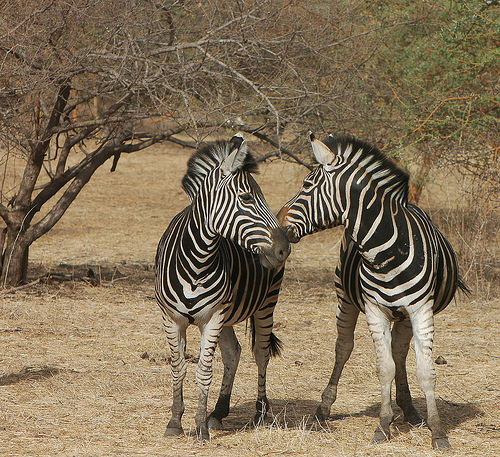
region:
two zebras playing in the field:
[181, 134, 416, 278]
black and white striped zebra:
[176, 132, 280, 439]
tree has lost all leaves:
[16, 30, 377, 127]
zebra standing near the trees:
[293, 130, 455, 394]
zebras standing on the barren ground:
[161, 139, 466, 445]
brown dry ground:
[27, 275, 153, 427]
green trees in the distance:
[231, 18, 484, 129]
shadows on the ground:
[159, 367, 498, 427]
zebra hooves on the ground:
[145, 379, 302, 448]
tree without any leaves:
[23, 66, 145, 304]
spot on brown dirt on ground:
[10, 353, 73, 397]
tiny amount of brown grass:
[244, 393, 326, 441]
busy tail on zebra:
[245, 326, 294, 362]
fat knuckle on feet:
[220, 337, 246, 367]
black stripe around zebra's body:
[153, 273, 220, 323]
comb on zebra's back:
[161, 118, 255, 194]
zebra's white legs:
[346, 287, 448, 420]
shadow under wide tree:
[6, 222, 157, 291]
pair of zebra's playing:
[138, 122, 498, 352]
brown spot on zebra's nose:
[257, 207, 316, 235]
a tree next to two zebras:
[2, 2, 307, 284]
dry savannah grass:
[2, 154, 496, 454]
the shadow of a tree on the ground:
[33, 255, 333, 293]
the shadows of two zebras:
[225, 391, 482, 443]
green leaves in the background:
[382, 4, 490, 89]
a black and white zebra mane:
[331, 129, 414, 201]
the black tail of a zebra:
[245, 309, 285, 361]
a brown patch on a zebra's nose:
[275, 204, 289, 224]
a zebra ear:
[220, 136, 253, 174]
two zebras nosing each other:
[149, 127, 488, 448]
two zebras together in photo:
[173, 148, 464, 279]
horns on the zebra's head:
[310, 140, 331, 165]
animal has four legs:
[153, 312, 282, 419]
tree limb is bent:
[44, 136, 161, 229]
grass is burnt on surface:
[16, 255, 148, 440]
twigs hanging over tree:
[116, 26, 295, 112]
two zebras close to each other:
[182, 173, 364, 255]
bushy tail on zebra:
[234, 325, 294, 355]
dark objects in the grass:
[80, 257, 133, 294]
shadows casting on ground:
[238, 396, 471, 431]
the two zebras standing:
[135, 127, 453, 446]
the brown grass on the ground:
[50, 312, 130, 454]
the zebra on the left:
[140, 128, 272, 434]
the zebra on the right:
[269, 128, 459, 451]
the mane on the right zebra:
[319, 130, 419, 199]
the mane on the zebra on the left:
[163, 143, 231, 204]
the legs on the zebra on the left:
[143, 304, 278, 444]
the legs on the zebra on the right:
[317, 277, 453, 446]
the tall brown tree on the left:
[4, 3, 245, 306]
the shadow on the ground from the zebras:
[222, 382, 496, 449]